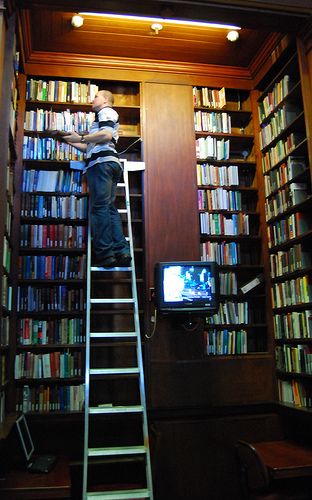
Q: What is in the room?
A: Ladder.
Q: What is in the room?
A: Shelf.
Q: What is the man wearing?
A: Shirt.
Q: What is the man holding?
A: Book.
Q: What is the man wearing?
A: Jeans.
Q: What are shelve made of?
A: Wood.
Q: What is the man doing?
A: Retrieving and returning books.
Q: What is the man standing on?
A: A ladder.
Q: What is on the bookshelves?
A: Books.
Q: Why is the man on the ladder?
A: To reach books on the higher shelves.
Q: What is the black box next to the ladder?
A: A television monitor.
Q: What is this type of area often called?
A: A library.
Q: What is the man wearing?
A: Short sleeved shirt, long pants, and shoes.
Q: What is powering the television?
A: Electricity.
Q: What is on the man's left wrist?
A: A wrist watch.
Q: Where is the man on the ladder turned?
A: To his left.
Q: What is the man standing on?
A: A ladder.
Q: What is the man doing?
A: Shelving books.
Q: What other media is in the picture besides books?
A: A television.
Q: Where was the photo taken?
A: In a library.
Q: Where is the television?
A: Beside the ladder.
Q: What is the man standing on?
A: A ladder.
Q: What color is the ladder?
A: Silver.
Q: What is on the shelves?
A: Books.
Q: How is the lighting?
A: Dark.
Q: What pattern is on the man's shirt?
A: Stripes.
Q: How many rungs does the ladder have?
A: 11.